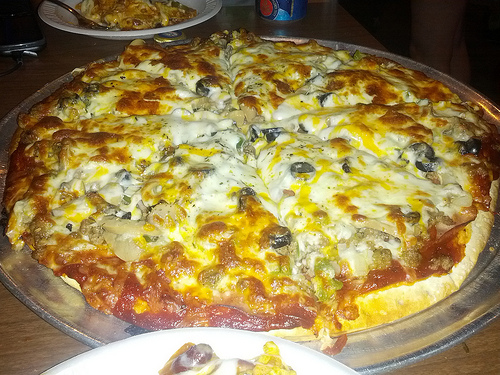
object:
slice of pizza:
[153, 338, 323, 374]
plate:
[37, 0, 225, 41]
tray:
[1, 35, 500, 375]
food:
[68, 0, 198, 31]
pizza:
[2, 22, 499, 346]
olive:
[290, 161, 316, 173]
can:
[256, 0, 306, 23]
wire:
[0, 51, 24, 79]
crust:
[74, 271, 227, 339]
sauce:
[408, 226, 470, 282]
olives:
[261, 126, 283, 144]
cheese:
[85, 67, 182, 162]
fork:
[46, 0, 108, 30]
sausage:
[427, 210, 478, 245]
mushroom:
[99, 218, 161, 239]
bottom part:
[256, 1, 309, 24]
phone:
[1, 2, 48, 58]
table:
[0, 3, 396, 124]